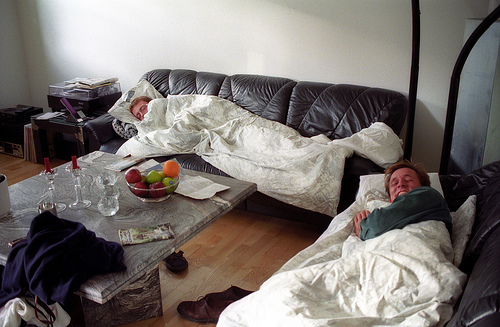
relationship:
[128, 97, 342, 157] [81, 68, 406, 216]
man in on top of couch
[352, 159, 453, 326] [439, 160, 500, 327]
man on top of couch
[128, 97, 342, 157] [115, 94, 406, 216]
man underneath blanket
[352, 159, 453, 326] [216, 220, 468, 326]
man underneath blanket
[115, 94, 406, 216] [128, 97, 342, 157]
blanket on top of man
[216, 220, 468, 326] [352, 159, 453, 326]
blanket on top of man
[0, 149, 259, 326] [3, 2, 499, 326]
coffee table in room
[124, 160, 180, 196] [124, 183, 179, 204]
fruit inside of bowl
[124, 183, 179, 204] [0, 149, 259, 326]
bowl on top of coffee table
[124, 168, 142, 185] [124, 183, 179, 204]
apple inside of bowl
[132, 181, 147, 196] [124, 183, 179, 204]
apple in inside of bowl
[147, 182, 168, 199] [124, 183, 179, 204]
apple inside of bowl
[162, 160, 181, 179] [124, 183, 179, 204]
fruit inside of bowl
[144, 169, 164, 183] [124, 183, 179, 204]
apple inside of bowl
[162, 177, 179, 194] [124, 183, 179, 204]
apple inside of bowl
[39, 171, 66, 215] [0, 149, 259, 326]
candlestick on top of coffee table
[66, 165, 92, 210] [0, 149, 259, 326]
candlestick on top of coffee table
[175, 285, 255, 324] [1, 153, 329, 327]
shoes are on top of floor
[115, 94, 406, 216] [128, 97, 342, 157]
blanket around man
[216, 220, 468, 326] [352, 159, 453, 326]
blanket around man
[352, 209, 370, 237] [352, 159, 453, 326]
fingers are part of man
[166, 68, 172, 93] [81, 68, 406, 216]
lines are part of couch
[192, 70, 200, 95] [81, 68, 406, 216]
lines are part of couch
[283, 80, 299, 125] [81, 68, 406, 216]
lines are part of couch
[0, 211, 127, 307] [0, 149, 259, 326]
clothing on top of coffee table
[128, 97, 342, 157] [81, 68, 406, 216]
man on top of couch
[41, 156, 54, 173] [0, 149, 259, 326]
candle on top of coffee table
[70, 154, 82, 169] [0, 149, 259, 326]
candle on top of coffee table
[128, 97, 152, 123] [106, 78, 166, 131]
head on top of pillow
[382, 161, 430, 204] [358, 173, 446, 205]
head on top of pillow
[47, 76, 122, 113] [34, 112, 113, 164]
record player on top of table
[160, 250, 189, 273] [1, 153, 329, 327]
sandal on top of floor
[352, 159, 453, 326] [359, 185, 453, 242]
man wearing shirt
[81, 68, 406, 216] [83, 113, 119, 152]
couch has arms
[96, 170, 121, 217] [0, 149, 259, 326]
glassware on top of coffee table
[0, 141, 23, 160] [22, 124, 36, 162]
stereo system next to records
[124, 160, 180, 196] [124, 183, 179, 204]
fruit in side of bowl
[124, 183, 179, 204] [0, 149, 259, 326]
bowl in on top of coffee table